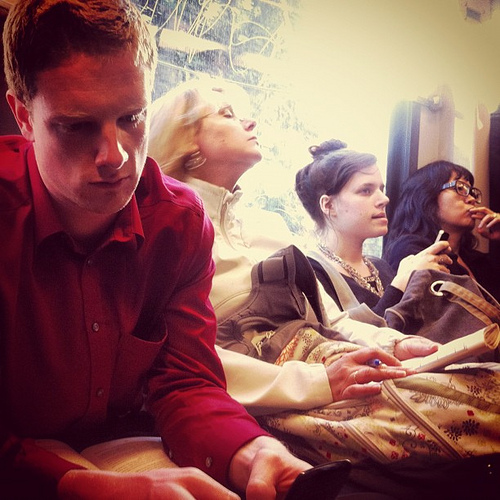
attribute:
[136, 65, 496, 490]
person — sitting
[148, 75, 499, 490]
lady — blonde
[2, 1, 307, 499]
person — sitting